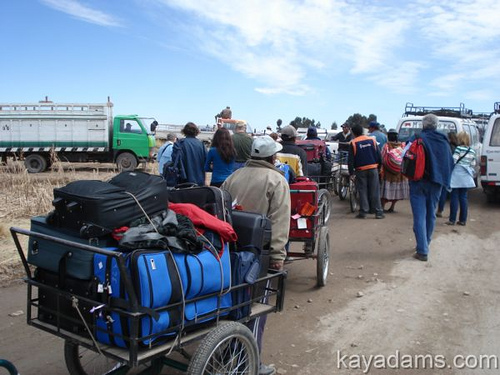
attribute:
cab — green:
[113, 116, 157, 162]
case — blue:
[93, 240, 234, 345]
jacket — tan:
[219, 159, 293, 266]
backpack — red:
[402, 137, 426, 181]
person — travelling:
[446, 133, 477, 226]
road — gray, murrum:
[261, 180, 500, 374]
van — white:
[396, 116, 483, 171]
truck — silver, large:
[1, 97, 157, 173]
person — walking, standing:
[347, 125, 386, 216]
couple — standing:
[171, 122, 237, 189]